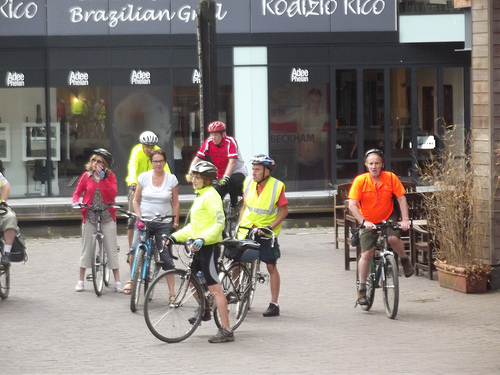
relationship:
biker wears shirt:
[348, 149, 409, 305] [345, 170, 410, 227]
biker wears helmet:
[120, 150, 180, 305] [137, 129, 161, 151]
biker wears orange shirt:
[348, 149, 409, 305] [348, 170, 406, 223]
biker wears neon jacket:
[232, 153, 289, 318] [232, 172, 283, 235]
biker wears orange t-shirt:
[232, 153, 289, 318] [255, 180, 263, 195]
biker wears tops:
[169, 160, 236, 344] [168, 184, 226, 246]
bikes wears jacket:
[126, 130, 172, 270] [124, 142, 170, 185]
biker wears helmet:
[186, 120, 250, 219] [208, 120, 226, 131]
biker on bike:
[186, 120, 250, 219] [198, 199, 267, 241]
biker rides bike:
[348, 149, 409, 305] [353, 220, 405, 315]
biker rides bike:
[232, 153, 289, 318] [228, 221, 275, 316]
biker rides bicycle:
[169, 160, 236, 344] [144, 237, 253, 343]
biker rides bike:
[120, 150, 180, 305] [124, 209, 181, 304]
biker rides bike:
[71, 147, 124, 295] [74, 197, 120, 299]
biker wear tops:
[169, 160, 236, 344] [164, 173, 290, 245]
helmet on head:
[207, 121, 227, 138] [250, 156, 275, 183]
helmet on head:
[249, 153, 279, 166] [208, 121, 227, 149]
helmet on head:
[137, 131, 162, 148] [188, 159, 220, 192]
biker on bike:
[71, 147, 124, 295] [68, 202, 126, 297]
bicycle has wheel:
[144, 237, 253, 343] [378, 252, 401, 319]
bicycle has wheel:
[356, 217, 406, 317] [142, 267, 205, 343]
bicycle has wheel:
[74, 204, 115, 296] [126, 247, 145, 307]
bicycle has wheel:
[122, 211, 174, 311] [90, 235, 103, 295]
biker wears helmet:
[169, 160, 236, 344] [238, 136, 292, 167]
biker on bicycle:
[169, 160, 236, 344] [356, 225, 406, 317]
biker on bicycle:
[348, 149, 409, 305] [144, 237, 253, 343]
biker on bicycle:
[232, 153, 289, 318] [74, 204, 115, 296]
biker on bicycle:
[120, 150, 180, 305] [122, 211, 174, 311]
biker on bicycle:
[71, 147, 124, 295] [231, 225, 276, 317]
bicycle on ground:
[356, 225, 406, 317] [1, 227, 498, 373]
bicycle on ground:
[144, 237, 253, 343] [1, 227, 498, 373]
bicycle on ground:
[74, 204, 115, 296] [1, 227, 498, 373]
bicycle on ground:
[122, 211, 174, 311] [1, 227, 498, 373]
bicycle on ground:
[231, 225, 276, 317] [1, 227, 498, 373]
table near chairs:
[342, 187, 457, 274] [326, 175, 418, 245]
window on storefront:
[2, 48, 229, 196] [3, 2, 470, 219]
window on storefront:
[269, 42, 459, 187] [3, 2, 470, 219]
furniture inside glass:
[334, 67, 389, 189] [447, 67, 467, 162]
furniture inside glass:
[416, 69, 467, 179] [417, 63, 437, 173]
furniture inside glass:
[172, 83, 234, 174] [389, 66, 414, 151]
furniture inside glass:
[334, 67, 389, 189] [365, 68, 388, 155]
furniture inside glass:
[416, 69, 467, 179] [338, 66, 360, 177]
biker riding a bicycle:
[348, 149, 409, 305] [353, 219, 405, 321]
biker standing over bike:
[169, 160, 237, 346] [142, 237, 262, 343]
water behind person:
[20, 211, 421, 233] [346, 149, 412, 301]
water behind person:
[20, 211, 421, 233] [235, 156, 284, 317]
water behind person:
[20, 211, 421, 233] [164, 158, 224, 317]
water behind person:
[20, 211, 421, 233] [187, 118, 246, 208]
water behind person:
[20, 211, 421, 233] [129, 151, 177, 302]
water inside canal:
[20, 211, 421, 233] [15, 189, 445, 231]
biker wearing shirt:
[348, 149, 409, 305] [337, 144, 432, 326]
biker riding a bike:
[348, 149, 409, 305] [350, 224, 400, 318]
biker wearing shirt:
[189, 118, 241, 185] [192, 132, 241, 189]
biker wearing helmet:
[189, 118, 241, 185] [205, 120, 231, 135]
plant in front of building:
[377, 108, 497, 289] [347, 14, 497, 286]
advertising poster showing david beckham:
[268, 66, 332, 189] [268, 87, 331, 192]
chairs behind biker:
[333, 183, 359, 270] [346, 146, 416, 319]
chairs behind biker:
[333, 183, 359, 270] [70, 146, 124, 296]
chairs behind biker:
[333, 183, 359, 270] [141, 158, 260, 343]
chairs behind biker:
[333, 183, 359, 270] [230, 154, 288, 316]